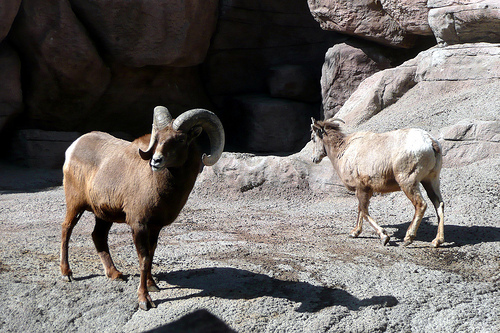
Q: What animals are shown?
A: Goats.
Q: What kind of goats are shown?
A: Mountain goats.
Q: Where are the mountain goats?
A: In a mountain.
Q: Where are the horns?
A: On the goats.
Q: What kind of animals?
A: Rams.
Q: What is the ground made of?
A: Rock.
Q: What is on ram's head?
A: Horns.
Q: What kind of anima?
A: Goat.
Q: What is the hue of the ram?
A: Brown.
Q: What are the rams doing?
A: Standing.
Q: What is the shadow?
A: Ram.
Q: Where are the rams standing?
A: Gravel.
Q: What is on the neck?
A: Brown.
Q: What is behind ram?
A: More rocks.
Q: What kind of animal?
A: Ram.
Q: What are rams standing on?
A: Gravel.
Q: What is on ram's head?
A: Horns.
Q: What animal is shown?
A: Rams.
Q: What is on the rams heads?
A: Horns.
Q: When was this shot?
A: Daytime.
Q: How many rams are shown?
A: 2.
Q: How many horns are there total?
A: 4.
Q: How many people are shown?
A: 0.